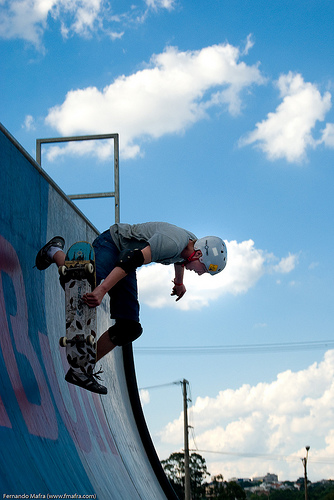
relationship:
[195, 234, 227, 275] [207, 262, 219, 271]
helmet with sticker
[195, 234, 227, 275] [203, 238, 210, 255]
helmet with sticker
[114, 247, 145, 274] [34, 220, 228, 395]
elbow pad worn by skater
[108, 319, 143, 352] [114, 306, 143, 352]
pad protecting knee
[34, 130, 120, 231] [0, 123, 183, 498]
handbar on ramp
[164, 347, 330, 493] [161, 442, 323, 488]
cloud near horizon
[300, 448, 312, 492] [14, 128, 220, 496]
post near ramp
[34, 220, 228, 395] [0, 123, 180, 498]
skater on ramp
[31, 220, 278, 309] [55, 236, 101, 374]
skater holds skateboard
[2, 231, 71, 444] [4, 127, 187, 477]
letter on ramp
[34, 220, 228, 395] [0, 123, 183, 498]
skater coming down ramp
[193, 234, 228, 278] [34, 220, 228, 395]
helmet worn by skater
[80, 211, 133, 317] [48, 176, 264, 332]
jeans worn by skater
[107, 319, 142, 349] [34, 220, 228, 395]
pad worn by skater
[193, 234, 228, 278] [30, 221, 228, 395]
helmet on person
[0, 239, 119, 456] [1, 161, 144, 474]
lettering on ramp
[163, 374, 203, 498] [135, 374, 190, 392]
pole has wires